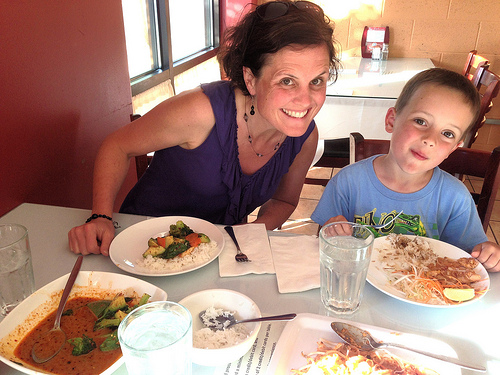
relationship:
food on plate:
[377, 232, 482, 300] [114, 211, 478, 320]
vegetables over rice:
[149, 221, 201, 254] [129, 245, 213, 279]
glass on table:
[333, 224, 380, 317] [27, 201, 402, 374]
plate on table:
[114, 211, 478, 320] [27, 201, 402, 374]